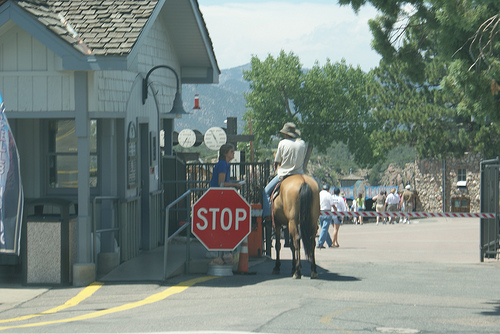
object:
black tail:
[298, 182, 315, 259]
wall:
[203, 137, 485, 224]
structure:
[2, 0, 223, 281]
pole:
[72, 70, 96, 287]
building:
[97, 9, 222, 261]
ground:
[361, 130, 431, 190]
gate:
[263, 159, 500, 264]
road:
[0, 211, 500, 333]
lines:
[0, 275, 220, 333]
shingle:
[95, 48, 107, 55]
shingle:
[61, 34, 81, 44]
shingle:
[38, 16, 62, 26]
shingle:
[114, 23, 132, 32]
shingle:
[136, 13, 150, 19]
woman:
[210, 143, 242, 187]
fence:
[161, 179, 246, 281]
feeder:
[192, 94, 201, 110]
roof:
[0, 0, 227, 84]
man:
[261, 122, 307, 226]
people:
[330, 187, 346, 247]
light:
[163, 93, 188, 118]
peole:
[316, 184, 337, 248]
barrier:
[319, 210, 495, 217]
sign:
[191, 186, 252, 251]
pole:
[207, 251, 234, 277]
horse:
[270, 152, 320, 279]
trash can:
[19, 200, 77, 287]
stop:
[196, 207, 247, 231]